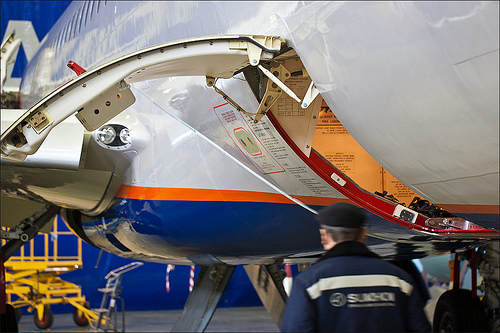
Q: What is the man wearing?
A: A hat.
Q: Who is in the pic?
A: A man.